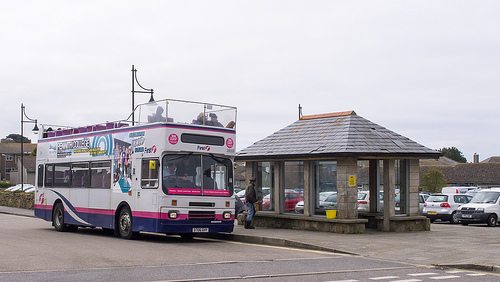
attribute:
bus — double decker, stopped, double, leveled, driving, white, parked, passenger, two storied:
[34, 96, 235, 243]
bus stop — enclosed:
[236, 105, 437, 234]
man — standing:
[242, 178, 260, 231]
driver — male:
[163, 163, 182, 181]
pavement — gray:
[300, 257, 377, 278]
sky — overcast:
[220, 4, 499, 103]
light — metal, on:
[15, 102, 44, 136]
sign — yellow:
[347, 173, 357, 189]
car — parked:
[420, 191, 474, 226]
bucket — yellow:
[323, 209, 339, 218]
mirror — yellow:
[146, 160, 159, 170]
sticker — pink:
[164, 130, 182, 144]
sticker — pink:
[226, 135, 235, 150]